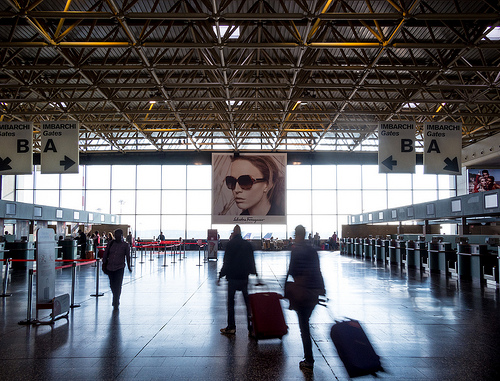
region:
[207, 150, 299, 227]
an image of a woman in the air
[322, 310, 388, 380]
a rolling suitcase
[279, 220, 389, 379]
a person pulling their suitcase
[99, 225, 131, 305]
a person walking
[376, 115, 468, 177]
signs on the roof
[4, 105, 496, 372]
an airport with people inside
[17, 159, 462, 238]
large windows looking outside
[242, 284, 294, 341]
large red suitcase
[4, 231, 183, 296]
red rope connecting the posts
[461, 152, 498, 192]
billboard on the wall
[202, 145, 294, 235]
large picture hanging from ceiling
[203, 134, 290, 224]
woman wearing sunglasses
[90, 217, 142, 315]
woman walking through airport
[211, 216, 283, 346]
man wearing hood on his head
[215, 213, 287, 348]
man pulling a large suitcase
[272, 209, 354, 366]
woman carrying a bag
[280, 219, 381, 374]
woman pulling a suitcase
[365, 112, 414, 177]
white sign with arrow on it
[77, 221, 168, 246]
people standing in line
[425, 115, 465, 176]
white sign with the letter A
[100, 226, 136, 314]
person in the terminal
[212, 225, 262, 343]
person in the terminal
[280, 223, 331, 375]
person in the terminal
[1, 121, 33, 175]
sign in the terminal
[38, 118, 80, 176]
sign in the terminal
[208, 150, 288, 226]
sign in the terminal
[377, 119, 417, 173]
sign in the terminal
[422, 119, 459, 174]
sign in the terminal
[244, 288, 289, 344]
suitcase carried by a person in the terminal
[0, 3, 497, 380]
Interior of an airport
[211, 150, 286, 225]
Advertisement with a woman wearing sunglasses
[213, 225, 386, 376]
Travelers rolling suitcases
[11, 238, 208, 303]
Ropes for forming lines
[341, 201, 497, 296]
ticketing gates at an airport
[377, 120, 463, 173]
Large white signs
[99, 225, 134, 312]
Silhouette of a man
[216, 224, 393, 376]
Silhouettes of two travelers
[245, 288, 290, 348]
Rolling luggage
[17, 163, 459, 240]
Large glass windows at an airport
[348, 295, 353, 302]
part of a floor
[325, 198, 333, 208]
part of a window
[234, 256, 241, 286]
part of a jacket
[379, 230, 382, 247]
edge of a rail